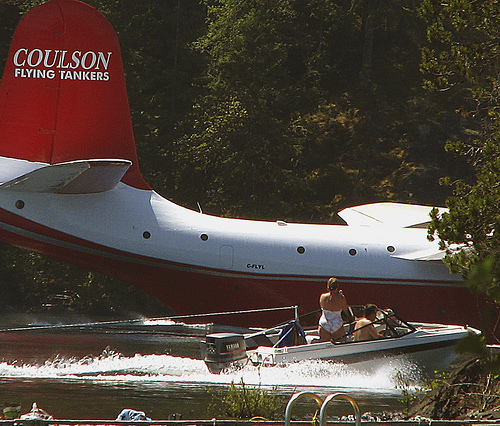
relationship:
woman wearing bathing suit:
[312, 275, 347, 343] [318, 307, 343, 334]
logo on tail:
[13, 42, 111, 82] [1, 0, 144, 183]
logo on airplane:
[13, 42, 111, 82] [0, 0, 500, 345]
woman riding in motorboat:
[312, 275, 347, 343] [182, 285, 486, 377]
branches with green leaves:
[432, 142, 497, 309] [433, 209, 484, 282]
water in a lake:
[32, 356, 177, 403] [12, 370, 201, 412]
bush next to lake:
[200, 369, 295, 424] [2, 346, 417, 392]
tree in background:
[177, 16, 412, 236] [9, 0, 417, 109]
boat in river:
[202, 289, 483, 389] [1, 301, 496, 423]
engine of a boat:
[195, 322, 249, 370] [202, 303, 483, 375]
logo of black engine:
[10, 42, 114, 112] [202, 330, 246, 382]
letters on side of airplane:
[242, 259, 269, 272] [0, 0, 500, 345]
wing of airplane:
[333, 201, 452, 230] [0, 0, 500, 345]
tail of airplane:
[1, 0, 144, 183] [28, 30, 454, 312]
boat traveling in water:
[202, 303, 483, 375] [1, 321, 499, 419]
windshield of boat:
[332, 300, 416, 338] [208, 303, 482, 377]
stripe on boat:
[310, 320, 482, 382] [204, 320, 484, 379]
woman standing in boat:
[312, 275, 347, 343] [198, 302, 483, 382]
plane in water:
[9, 18, 498, 339] [84, 340, 216, 407]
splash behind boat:
[5, 340, 425, 412] [202, 303, 483, 375]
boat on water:
[201, 306, 483, 393] [1, 321, 499, 419]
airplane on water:
[16, 187, 373, 267] [6, 302, 494, 424]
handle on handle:
[316, 392, 360, 424] [281, 391, 325, 425]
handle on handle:
[283, 391, 321, 423] [281, 391, 325, 425]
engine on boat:
[199, 333, 248, 375] [207, 306, 469, 358]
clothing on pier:
[117, 407, 150, 420] [6, 405, 341, 424]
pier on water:
[7, 394, 499, 424] [6, 302, 494, 424]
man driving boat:
[352, 306, 379, 341] [204, 320, 484, 373]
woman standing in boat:
[312, 275, 344, 342] [202, 289, 483, 389]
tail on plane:
[1, 0, 155, 190] [9, 18, 498, 339]